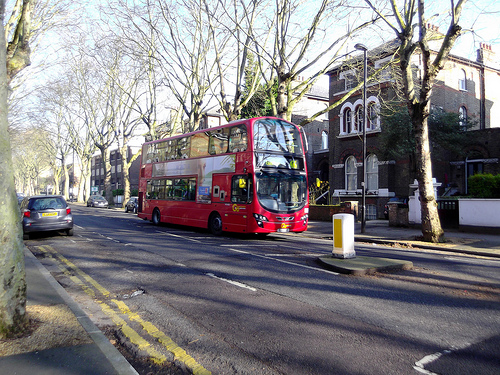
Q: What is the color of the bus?
A: Red.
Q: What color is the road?
A: Gray.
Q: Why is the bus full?
A: People must travel.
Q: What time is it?
A: Daytime.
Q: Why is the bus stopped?
A: To pick up passengers.